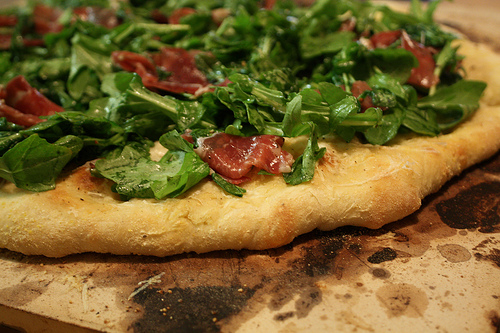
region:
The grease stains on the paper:
[123, 269, 255, 331]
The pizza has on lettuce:
[95, 128, 225, 198]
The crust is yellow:
[6, 197, 128, 249]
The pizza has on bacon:
[200, 115, 292, 166]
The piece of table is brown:
[0, 298, 91, 332]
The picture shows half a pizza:
[4, 6, 493, 267]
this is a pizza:
[16, 11, 487, 311]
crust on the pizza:
[29, 113, 480, 274]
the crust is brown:
[10, 118, 498, 278]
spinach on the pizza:
[8, 15, 485, 212]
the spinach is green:
[15, 18, 431, 197]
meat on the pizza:
[168, 103, 317, 208]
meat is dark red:
[171, 110, 328, 192]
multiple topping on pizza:
[3, 2, 465, 231]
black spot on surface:
[78, 253, 233, 328]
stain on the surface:
[280, 227, 438, 329]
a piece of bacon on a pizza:
[208, 131, 280, 179]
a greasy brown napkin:
[0, 148, 498, 330]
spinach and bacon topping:
[3, 0, 480, 199]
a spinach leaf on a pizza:
[25, 33, 120, 91]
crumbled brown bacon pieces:
[113, 43, 205, 96]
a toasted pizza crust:
[0, 39, 499, 256]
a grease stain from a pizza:
[440, 168, 497, 241]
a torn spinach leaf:
[109, 157, 200, 199]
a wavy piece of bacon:
[203, 137, 282, 179]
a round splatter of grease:
[434, 242, 471, 264]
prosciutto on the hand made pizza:
[0, 76, 83, 136]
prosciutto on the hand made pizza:
[186, 124, 296, 181]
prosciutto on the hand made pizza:
[115, 43, 219, 102]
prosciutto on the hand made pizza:
[398, 33, 444, 93]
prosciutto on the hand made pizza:
[341, 78, 375, 109]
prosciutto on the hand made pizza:
[30, 2, 67, 42]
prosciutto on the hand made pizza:
[78, 5, 130, 32]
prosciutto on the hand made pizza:
[155, 8, 200, 30]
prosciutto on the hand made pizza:
[255, 0, 275, 13]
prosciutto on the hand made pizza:
[357, 24, 401, 55]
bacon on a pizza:
[214, 135, 291, 167]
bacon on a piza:
[125, 51, 192, 91]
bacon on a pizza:
[4, 65, 61, 116]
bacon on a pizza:
[407, 35, 440, 86]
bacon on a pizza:
[28, 6, 68, 33]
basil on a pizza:
[93, 137, 187, 192]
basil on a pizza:
[217, 83, 254, 118]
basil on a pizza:
[325, 91, 389, 131]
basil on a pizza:
[62, 35, 97, 81]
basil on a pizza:
[122, 14, 187, 38]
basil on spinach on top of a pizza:
[46, 14, 420, 155]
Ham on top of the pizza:
[204, 120, 281, 166]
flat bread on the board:
[48, 150, 411, 289]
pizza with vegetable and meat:
[21, 19, 482, 238]